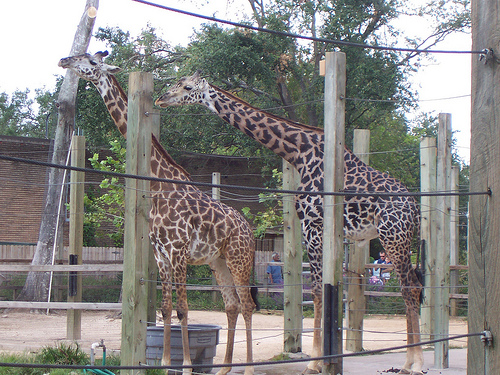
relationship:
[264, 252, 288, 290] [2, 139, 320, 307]
man standing in front building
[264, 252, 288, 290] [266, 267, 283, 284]
man wearing shirt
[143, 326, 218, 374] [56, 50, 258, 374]
trash can behind giraffe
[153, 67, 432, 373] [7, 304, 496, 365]
giraffe are standing on ground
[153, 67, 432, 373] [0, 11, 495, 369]
giraffe are standing in zoo pen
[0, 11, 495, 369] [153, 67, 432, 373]
fence surrounds giraffe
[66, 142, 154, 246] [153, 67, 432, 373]
tree behind giraffe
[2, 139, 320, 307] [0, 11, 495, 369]
building behind zoo pen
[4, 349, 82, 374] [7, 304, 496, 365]
grass on ground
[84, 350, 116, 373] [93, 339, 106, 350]
garden hose attached to faucet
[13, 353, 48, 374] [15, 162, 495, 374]
bushes by fence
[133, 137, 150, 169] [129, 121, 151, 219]
hole in wood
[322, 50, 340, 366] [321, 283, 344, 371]
post has a bottom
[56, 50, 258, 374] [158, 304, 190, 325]
giraffe has knees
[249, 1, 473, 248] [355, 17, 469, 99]
tree has branch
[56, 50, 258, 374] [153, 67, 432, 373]
giraffe standing next to giraffe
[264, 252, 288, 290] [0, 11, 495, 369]
man standing behind zoo pen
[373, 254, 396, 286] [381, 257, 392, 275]
man holding child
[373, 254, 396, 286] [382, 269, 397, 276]
man has arms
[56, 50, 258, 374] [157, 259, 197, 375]
giraffe has two front legs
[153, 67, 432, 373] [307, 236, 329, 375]
giraffe has two front legs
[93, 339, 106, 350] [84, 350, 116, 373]
faucet next to garden hose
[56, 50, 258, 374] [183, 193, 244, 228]
giraffe has a back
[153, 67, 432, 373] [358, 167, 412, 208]
giraffe has a back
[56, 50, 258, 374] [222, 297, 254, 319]
giraffe has knees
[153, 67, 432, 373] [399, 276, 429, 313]
giraffe has knees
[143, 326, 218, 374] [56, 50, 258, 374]
plastic container behind giraffe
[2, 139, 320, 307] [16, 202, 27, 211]
building made of brick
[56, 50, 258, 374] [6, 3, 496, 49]
giraffe looking up at sky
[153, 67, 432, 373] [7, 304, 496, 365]
giraffe looking down at ground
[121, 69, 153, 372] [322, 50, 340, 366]
pole links to another pole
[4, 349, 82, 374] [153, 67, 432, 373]
grass in front of giraffe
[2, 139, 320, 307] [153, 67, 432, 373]
building behind giraffe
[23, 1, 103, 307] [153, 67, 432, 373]
tree trunk behind giraffe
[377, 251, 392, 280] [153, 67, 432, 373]
people are looking at giraffe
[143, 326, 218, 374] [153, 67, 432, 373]
water bucket behind giraffe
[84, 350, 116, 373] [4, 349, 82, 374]
garden hose lying on top grass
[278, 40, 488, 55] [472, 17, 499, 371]
rods are connected to post